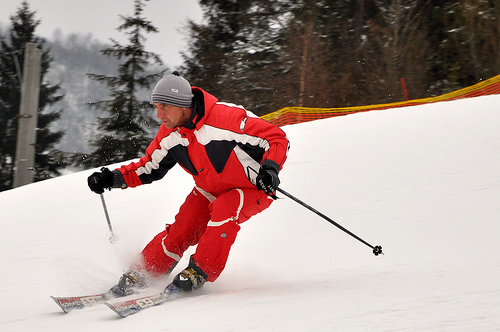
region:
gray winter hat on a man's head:
[149, 69, 194, 106]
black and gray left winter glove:
[253, 158, 279, 193]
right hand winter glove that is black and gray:
[85, 166, 117, 195]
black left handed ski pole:
[245, 162, 387, 258]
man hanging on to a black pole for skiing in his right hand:
[98, 190, 118, 245]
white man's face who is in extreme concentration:
[150, 99, 192, 131]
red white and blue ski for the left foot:
[105, 291, 165, 318]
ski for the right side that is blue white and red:
[45, 289, 109, 316]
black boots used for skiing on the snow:
[115, 266, 206, 294]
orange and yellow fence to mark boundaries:
[262, 71, 498, 128]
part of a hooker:
[328, 205, 362, 247]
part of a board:
[127, 286, 147, 308]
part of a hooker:
[354, 211, 393, 268]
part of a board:
[138, 291, 170, 326]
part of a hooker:
[306, 184, 343, 233]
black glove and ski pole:
[244, 165, 393, 264]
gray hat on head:
[134, 68, 217, 110]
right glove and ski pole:
[78, 158, 135, 251]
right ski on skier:
[45, 286, 153, 309]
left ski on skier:
[108, 268, 222, 323]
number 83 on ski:
[137, 296, 156, 311]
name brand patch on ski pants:
[218, 231, 228, 237]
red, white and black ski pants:
[117, 100, 292, 285]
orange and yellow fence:
[234, 20, 423, 170]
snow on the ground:
[382, 133, 483, 315]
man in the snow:
[41, 60, 391, 315]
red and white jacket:
[67, 69, 336, 280]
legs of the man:
[141, 200, 251, 275]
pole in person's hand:
[265, 151, 418, 277]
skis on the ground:
[43, 250, 229, 322]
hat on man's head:
[142, 62, 202, 120]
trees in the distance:
[230, 2, 378, 79]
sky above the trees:
[55, 2, 112, 31]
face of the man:
[139, 85, 187, 133]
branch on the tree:
[270, 36, 333, 94]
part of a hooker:
[290, 201, 312, 259]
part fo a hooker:
[353, 216, 384, 284]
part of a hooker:
[340, 219, 373, 295]